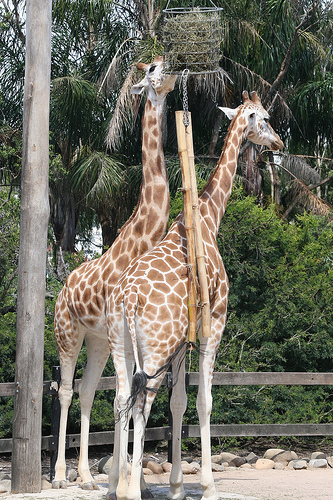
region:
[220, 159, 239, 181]
neck of the giraffe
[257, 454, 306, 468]
rocks on the ground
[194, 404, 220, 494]
leg of the giraffe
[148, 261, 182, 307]
the pattern on the giraffe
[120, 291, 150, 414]
The giraffes tail is long.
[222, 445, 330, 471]
The rocks are on the ground.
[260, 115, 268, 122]
The giraffes eye is black in color.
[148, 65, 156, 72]
The giraffes eye is round.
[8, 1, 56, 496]
The tree trunk is tall.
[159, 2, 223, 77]
The hay is in the basket.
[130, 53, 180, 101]
The giraffe is eating from the basket.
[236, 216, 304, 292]
The trees in the background are green.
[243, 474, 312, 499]
The ground is light brown in color.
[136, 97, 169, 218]
The giraffe has a long neck.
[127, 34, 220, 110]
the giraffe is eating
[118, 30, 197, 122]
the giraffe is eating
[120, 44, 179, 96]
the giraffe is eating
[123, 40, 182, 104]
the giraffe is eating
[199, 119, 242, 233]
giraffe's neck is long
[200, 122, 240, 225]
giraffe's neck is long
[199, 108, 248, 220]
giraffe's neck is long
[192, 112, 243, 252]
giraffe's neck is long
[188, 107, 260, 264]
giraffe's neck is long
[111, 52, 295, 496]
this is a giraffe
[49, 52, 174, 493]
this is a giraffe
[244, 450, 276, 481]
this is a small rock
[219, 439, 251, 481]
this is a small rock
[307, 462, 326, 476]
this is a small rock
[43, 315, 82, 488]
the leg of a giraffe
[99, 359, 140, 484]
the leg of a giraffe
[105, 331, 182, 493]
the leg of a giraffe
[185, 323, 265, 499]
the leg of a giraffe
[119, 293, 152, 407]
The giraffe has a long tail.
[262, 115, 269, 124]
The giraffes eye is black.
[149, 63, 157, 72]
The giraffes eye is black.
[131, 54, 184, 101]
The giraffe is eating.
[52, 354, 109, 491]
The giraffe has long legs.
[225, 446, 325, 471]
The rocks are on the ground.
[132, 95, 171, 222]
The giraffe's neck is long.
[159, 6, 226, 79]
The basket is full of hay.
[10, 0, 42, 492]
The tree trunk is tall.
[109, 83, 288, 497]
this is a giraffe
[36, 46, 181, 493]
this is a giraffe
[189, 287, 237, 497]
the leg of a giraffe